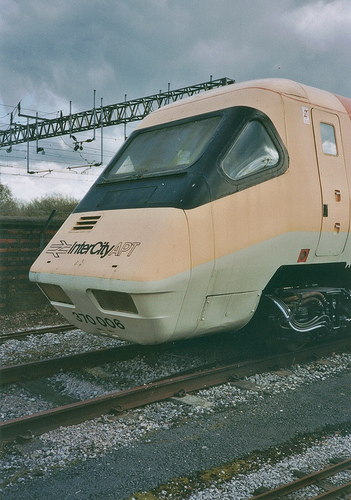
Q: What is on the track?
A: A train.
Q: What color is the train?
A: Orange.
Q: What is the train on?
A: The track.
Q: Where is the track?
A: Under the train.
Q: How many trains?
A: 1.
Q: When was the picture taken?
A: Daytime.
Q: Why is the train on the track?
A: Traveling.